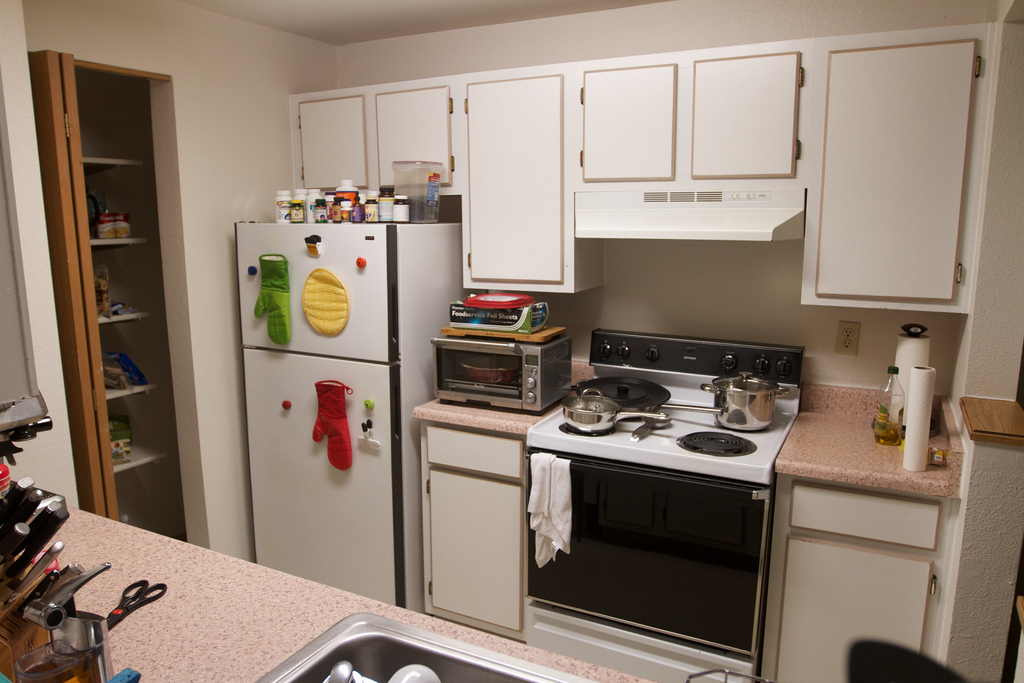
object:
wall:
[364, 26, 462, 77]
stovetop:
[525, 363, 801, 486]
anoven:
[520, 584, 758, 682]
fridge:
[243, 347, 437, 616]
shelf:
[87, 353, 158, 400]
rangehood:
[573, 187, 806, 241]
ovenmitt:
[254, 253, 290, 345]